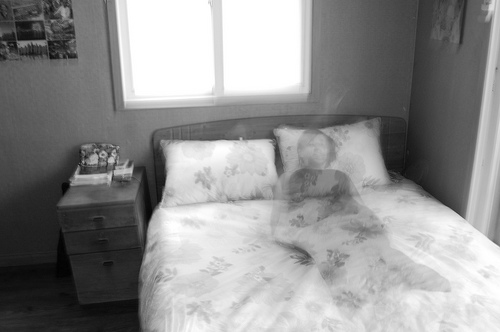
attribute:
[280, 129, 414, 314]
figure — shadowy, woman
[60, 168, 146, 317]
nightstand — wooden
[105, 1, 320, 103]
window — daytime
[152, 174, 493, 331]
sheets — white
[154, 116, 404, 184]
headboard — simple